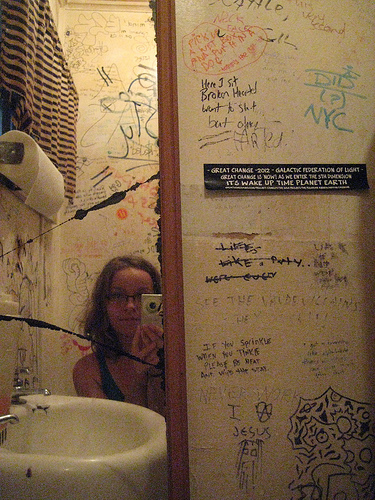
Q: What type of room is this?
A: It is a bathroom.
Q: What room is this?
A: It is a bathroom.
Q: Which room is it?
A: It is a bathroom.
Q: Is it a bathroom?
A: Yes, it is a bathroom.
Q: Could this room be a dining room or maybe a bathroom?
A: It is a bathroom.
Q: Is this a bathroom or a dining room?
A: It is a bathroom.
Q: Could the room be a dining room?
A: No, it is a bathroom.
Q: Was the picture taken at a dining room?
A: No, the picture was taken in a bathroom.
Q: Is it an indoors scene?
A: Yes, it is indoors.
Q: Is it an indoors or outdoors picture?
A: It is indoors.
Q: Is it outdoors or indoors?
A: It is indoors.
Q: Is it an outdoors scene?
A: No, it is indoors.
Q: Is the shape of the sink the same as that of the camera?
A: Yes, both the sink and the camera are round.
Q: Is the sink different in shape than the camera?
A: No, both the sink and the camera are round.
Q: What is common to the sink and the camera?
A: The shape, both the sink and the camera are round.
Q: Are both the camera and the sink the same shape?
A: Yes, both the camera and the sink are round.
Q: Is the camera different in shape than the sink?
A: No, both the camera and the sink are round.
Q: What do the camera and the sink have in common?
A: The shape, both the camera and the sink are round.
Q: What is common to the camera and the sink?
A: The shape, both the camera and the sink are round.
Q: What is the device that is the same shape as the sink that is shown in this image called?
A: The device is a camera.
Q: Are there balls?
A: No, there are no balls.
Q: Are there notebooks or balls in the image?
A: No, there are no balls or notebooks.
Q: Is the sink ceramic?
A: Yes, the sink is ceramic.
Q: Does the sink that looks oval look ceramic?
A: Yes, the sink is ceramic.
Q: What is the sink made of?
A: The sink is made of porcelain.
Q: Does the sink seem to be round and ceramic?
A: Yes, the sink is round and ceramic.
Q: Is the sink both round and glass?
A: No, the sink is round but ceramic.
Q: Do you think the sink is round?
A: Yes, the sink is round.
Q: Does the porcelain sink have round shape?
A: Yes, the sink is round.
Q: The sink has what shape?
A: The sink is round.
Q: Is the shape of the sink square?
A: No, the sink is round.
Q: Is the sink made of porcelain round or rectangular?
A: The sink is round.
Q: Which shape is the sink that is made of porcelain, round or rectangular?
A: The sink is round.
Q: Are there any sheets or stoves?
A: No, there are no sheets or stoves.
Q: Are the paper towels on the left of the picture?
A: Yes, the paper towels are on the left of the image.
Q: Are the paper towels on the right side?
A: No, the paper towels are on the left of the image.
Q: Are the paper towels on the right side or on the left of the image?
A: The paper towels are on the left of the image.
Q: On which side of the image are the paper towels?
A: The paper towels are on the left of the image.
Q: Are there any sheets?
A: No, there are no sheets.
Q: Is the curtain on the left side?
A: Yes, the curtain is on the left of the image.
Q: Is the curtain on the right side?
A: No, the curtain is on the left of the image.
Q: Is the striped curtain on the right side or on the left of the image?
A: The curtain is on the left of the image.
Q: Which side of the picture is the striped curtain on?
A: The curtain is on the left of the image.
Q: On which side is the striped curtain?
A: The curtain is on the left of the image.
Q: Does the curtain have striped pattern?
A: Yes, the curtain is striped.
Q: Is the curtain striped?
A: Yes, the curtain is striped.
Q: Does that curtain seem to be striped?
A: Yes, the curtain is striped.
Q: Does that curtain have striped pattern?
A: Yes, the curtain is striped.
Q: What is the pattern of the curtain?
A: The curtain is striped.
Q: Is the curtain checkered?
A: No, the curtain is striped.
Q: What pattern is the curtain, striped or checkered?
A: The curtain is striped.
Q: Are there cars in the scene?
A: No, there are no cars.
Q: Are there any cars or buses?
A: No, there are no cars or buses.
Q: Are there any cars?
A: No, there are no cars.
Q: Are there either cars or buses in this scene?
A: No, there are no cars or buses.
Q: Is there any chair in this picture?
A: No, there are no chairs.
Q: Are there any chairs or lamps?
A: No, there are no chairs or lamps.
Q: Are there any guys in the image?
A: No, there are no guys.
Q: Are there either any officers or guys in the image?
A: No, there are no guys or officers.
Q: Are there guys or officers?
A: No, there are no guys or officers.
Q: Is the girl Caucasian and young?
A: Yes, the girl is Caucasian and young.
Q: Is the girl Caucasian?
A: Yes, the girl is caucasian.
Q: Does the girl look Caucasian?
A: Yes, the girl is caucasian.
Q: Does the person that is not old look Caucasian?
A: Yes, the girl is caucasian.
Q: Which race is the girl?
A: The girl is caucasian.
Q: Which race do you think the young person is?
A: The girl is caucasian.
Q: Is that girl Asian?
A: No, the girl is caucasian.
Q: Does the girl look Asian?
A: No, the girl is caucasian.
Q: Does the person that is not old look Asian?
A: No, the girl is caucasian.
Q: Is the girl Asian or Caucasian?
A: The girl is caucasian.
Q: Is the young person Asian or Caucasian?
A: The girl is caucasian.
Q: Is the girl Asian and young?
A: No, the girl is young but caucasian.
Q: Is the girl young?
A: Yes, the girl is young.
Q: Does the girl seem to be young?
A: Yes, the girl is young.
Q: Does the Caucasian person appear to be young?
A: Yes, the girl is young.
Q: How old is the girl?
A: The girl is young.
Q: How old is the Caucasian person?
A: The girl is young.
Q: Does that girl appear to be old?
A: No, the girl is young.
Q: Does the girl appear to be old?
A: No, the girl is young.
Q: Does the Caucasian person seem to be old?
A: No, the girl is young.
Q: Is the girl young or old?
A: The girl is young.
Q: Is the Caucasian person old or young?
A: The girl is young.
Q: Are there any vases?
A: No, there are no vases.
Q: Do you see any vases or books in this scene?
A: No, there are no vases or books.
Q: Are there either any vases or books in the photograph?
A: No, there are no vases or books.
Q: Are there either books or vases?
A: No, there are no vases or books.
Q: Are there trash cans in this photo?
A: No, there are no trash cans.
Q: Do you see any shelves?
A: No, there are no shelves.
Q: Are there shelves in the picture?
A: No, there are no shelves.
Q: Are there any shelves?
A: No, there are no shelves.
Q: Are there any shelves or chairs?
A: No, there are no shelves or chairs.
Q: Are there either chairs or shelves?
A: No, there are no shelves or chairs.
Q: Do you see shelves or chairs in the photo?
A: No, there are no shelves or chairs.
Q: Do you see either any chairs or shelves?
A: No, there are no shelves or chairs.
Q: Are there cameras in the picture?
A: Yes, there is a camera.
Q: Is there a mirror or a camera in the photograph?
A: Yes, there is a camera.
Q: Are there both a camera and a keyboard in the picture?
A: No, there is a camera but no keyboards.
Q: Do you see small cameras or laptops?
A: Yes, there is a small camera.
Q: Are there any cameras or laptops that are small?
A: Yes, the camera is small.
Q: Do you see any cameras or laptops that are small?
A: Yes, the camera is small.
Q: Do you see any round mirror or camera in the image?
A: Yes, there is a round camera.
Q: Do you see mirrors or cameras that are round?
A: Yes, the camera is round.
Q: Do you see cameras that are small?
A: Yes, there is a small camera.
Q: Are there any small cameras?
A: Yes, there is a small camera.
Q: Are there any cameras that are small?
A: Yes, there is a camera that is small.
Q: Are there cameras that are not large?
A: Yes, there is a small camera.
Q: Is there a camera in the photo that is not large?
A: Yes, there is a small camera.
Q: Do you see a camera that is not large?
A: Yes, there is a small camera.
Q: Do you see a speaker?
A: No, there are no speakers.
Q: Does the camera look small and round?
A: Yes, the camera is small and round.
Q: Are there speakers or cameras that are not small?
A: No, there is a camera but it is small.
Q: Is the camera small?
A: Yes, the camera is small.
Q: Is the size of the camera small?
A: Yes, the camera is small.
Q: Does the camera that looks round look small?
A: Yes, the camera is small.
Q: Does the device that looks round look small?
A: Yes, the camera is small.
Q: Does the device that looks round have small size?
A: Yes, the camera is small.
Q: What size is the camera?
A: The camera is small.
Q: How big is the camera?
A: The camera is small.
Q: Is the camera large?
A: No, the camera is small.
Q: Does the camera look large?
A: No, the camera is small.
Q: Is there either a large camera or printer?
A: No, there is a camera but it is small.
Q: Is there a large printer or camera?
A: No, there is a camera but it is small.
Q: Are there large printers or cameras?
A: No, there is a camera but it is small.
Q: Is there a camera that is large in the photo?
A: No, there is a camera but it is small.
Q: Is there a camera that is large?
A: No, there is a camera but it is small.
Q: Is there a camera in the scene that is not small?
A: No, there is a camera but it is small.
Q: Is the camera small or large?
A: The camera is small.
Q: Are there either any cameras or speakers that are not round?
A: No, there is a camera but it is round.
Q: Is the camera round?
A: Yes, the camera is round.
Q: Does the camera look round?
A: Yes, the camera is round.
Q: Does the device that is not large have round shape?
A: Yes, the camera is round.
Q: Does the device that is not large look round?
A: Yes, the camera is round.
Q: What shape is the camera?
A: The camera is round.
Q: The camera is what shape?
A: The camera is round.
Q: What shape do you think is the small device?
A: The camera is round.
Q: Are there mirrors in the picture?
A: Yes, there is a mirror.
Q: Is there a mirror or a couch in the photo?
A: Yes, there is a mirror.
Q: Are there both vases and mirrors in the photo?
A: No, there is a mirror but no vases.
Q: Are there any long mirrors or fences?
A: Yes, there is a long mirror.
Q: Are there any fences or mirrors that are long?
A: Yes, the mirror is long.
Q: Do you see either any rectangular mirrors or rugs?
A: Yes, there is a rectangular mirror.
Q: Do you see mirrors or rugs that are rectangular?
A: Yes, the mirror is rectangular.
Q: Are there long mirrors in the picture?
A: Yes, there is a long mirror.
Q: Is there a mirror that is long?
A: Yes, there is a mirror that is long.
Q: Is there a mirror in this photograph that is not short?
A: Yes, there is a long mirror.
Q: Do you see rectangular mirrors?
A: Yes, there is a rectangular mirror.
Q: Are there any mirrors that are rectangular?
A: Yes, there is a mirror that is rectangular.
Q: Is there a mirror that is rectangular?
A: Yes, there is a mirror that is rectangular.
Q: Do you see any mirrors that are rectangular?
A: Yes, there is a mirror that is rectangular.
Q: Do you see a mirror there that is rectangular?
A: Yes, there is a mirror that is rectangular.